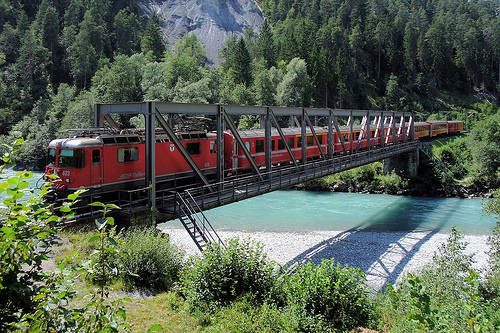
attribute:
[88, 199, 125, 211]
leaf — green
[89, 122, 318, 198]
train — red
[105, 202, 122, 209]
leaf — green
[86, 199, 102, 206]
leaf — green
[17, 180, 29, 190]
leaf — green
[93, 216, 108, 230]
leaf — green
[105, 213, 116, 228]
leaf — green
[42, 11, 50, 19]
leaf — green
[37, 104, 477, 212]
train — red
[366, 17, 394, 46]
leaf — green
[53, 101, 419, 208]
train — red